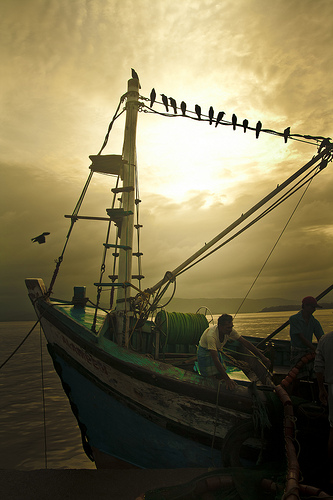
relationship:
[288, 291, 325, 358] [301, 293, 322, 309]
man wearing hat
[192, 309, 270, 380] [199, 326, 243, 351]
man wearing shirt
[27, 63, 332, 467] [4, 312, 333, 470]
boat in ocean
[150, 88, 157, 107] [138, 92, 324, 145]
bird on line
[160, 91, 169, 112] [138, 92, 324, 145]
bird on line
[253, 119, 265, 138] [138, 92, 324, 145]
bird on line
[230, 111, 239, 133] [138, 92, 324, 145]
bird on line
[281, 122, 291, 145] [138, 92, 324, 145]
bird on line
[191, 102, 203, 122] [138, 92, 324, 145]
bird on line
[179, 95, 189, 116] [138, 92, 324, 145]
bird on line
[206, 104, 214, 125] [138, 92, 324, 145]
bird on line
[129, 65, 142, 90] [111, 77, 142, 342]
bird top of mast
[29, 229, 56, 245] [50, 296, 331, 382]
bird landing on deck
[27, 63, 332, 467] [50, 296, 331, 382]
boat has deck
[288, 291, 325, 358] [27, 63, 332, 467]
man on boat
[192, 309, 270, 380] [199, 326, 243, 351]
man in shirt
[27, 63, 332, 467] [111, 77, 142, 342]
boat has mast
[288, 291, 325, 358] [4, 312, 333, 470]
man looks at ocean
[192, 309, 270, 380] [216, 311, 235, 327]
man has hair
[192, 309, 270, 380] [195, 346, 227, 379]
man wearing apron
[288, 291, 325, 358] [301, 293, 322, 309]
man in hat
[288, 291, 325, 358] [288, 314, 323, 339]
man in shirt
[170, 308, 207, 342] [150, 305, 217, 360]
rope on spool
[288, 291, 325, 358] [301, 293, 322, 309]
man has cap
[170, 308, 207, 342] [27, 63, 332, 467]
rope on boat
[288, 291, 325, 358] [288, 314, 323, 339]
man wearing shirt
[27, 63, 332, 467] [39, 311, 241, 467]
boat has side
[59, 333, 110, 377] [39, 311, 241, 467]
letters on side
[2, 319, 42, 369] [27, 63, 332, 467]
rope front of boat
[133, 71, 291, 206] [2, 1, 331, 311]
sun in sky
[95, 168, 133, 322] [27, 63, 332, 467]
ladder on boat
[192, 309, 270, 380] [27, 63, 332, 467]
man on boat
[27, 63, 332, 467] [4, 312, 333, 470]
boat on ocean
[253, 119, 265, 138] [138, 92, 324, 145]
bird perched on line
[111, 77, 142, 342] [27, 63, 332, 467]
mast on boat